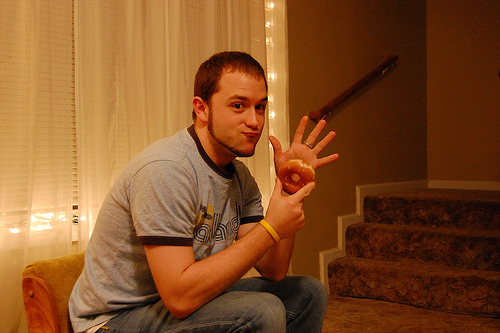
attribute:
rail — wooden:
[310, 55, 397, 120]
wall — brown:
[288, 2, 499, 191]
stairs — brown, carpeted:
[328, 194, 500, 320]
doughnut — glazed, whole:
[277, 160, 315, 194]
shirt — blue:
[68, 125, 263, 332]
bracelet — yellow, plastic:
[260, 220, 280, 244]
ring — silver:
[302, 140, 312, 148]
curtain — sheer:
[1, 1, 71, 256]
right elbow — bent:
[163, 307, 202, 320]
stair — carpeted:
[329, 257, 499, 317]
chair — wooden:
[23, 250, 87, 333]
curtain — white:
[75, 1, 191, 126]